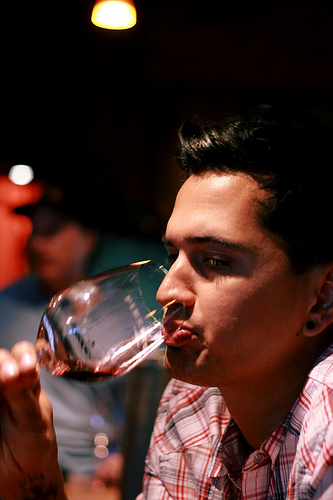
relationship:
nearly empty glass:
[33, 258, 182, 382] [30, 254, 191, 385]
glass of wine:
[30, 254, 191, 385] [33, 302, 118, 391]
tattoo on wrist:
[16, 475, 64, 499] [8, 466, 66, 499]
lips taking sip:
[160, 320, 194, 350] [149, 312, 198, 361]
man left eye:
[134, 118, 329, 493] [187, 239, 237, 295]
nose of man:
[154, 252, 197, 310] [0, 118, 331, 498]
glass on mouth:
[30, 254, 191, 385] [160, 320, 194, 350]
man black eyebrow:
[0, 118, 331, 498] [184, 230, 252, 259]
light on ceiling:
[86, 1, 140, 37] [6, 3, 331, 153]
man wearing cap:
[0, 180, 168, 490] [19, 179, 93, 229]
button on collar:
[250, 452, 273, 469] [198, 419, 298, 498]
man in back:
[0, 180, 168, 490] [4, 3, 329, 277]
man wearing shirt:
[0, 180, 168, 490] [6, 278, 151, 471]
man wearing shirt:
[0, 118, 331, 498] [134, 349, 330, 500]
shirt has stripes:
[134, 349, 330, 500] [134, 351, 332, 499]